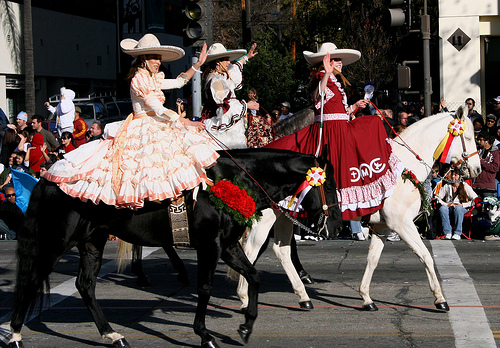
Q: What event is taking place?
A: A parade.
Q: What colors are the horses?
A: Black and white.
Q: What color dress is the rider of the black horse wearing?
A: Pink.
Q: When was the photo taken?
A: During the day.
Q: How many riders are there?
A: 3.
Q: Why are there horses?
A: Because of the parade.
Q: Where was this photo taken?
A: At a parade.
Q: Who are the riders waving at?
A: The crowd.